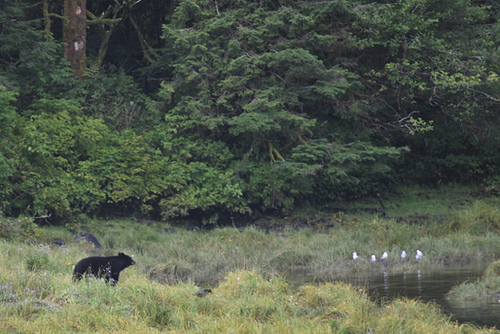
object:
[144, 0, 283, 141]
tree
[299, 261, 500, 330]
water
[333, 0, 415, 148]
tree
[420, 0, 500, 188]
tree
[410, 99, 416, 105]
leaves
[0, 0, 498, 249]
forest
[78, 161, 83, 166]
leaves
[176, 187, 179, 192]
leaves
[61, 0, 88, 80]
tree trunk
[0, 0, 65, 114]
tree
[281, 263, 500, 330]
creek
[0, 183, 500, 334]
field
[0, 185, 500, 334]
grass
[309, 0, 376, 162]
trees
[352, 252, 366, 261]
bird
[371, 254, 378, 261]
bird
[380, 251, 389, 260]
bird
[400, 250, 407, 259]
bird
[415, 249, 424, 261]
bird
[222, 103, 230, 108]
leaves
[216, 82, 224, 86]
leaves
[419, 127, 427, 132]
leaves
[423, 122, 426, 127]
leaves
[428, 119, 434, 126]
leaves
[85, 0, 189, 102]
tree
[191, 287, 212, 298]
bird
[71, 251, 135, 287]
bear